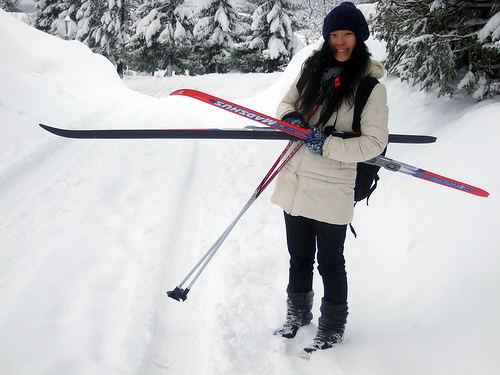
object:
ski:
[169, 88, 489, 197]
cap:
[322, 1, 370, 41]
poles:
[166, 139, 307, 304]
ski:
[37, 124, 435, 143]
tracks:
[0, 128, 199, 375]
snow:
[0, 0, 500, 375]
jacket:
[269, 50, 388, 226]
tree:
[244, 0, 299, 73]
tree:
[189, 1, 240, 76]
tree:
[132, 1, 192, 77]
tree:
[86, 0, 139, 77]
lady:
[271, 0, 388, 355]